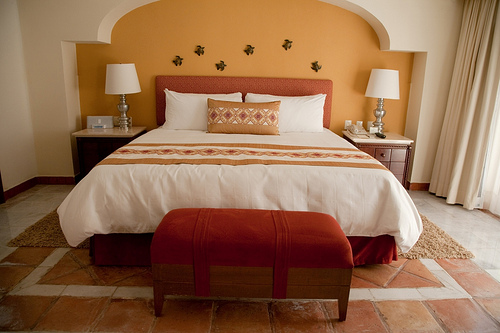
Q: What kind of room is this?
A: A bedroom.